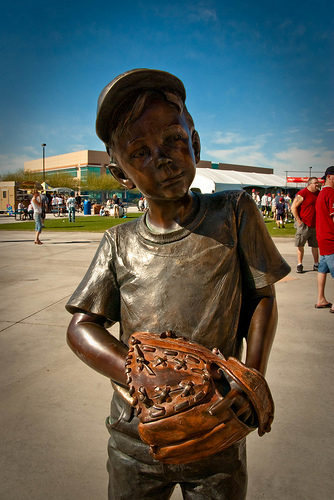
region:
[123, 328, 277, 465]
baseball mit on the statue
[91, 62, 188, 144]
hat on the boy's head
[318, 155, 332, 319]
man standing in the background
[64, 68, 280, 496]
copper color statue of a boy baseball player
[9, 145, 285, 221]
building in the background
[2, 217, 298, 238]
large green grassy field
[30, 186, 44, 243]
a woman standing on the sidewalk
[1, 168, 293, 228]
crowd of people in the distance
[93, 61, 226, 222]
the boy statue is looking to the right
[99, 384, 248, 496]
jean paths on the boy statue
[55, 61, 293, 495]
A statue of a young boy with a pitching glove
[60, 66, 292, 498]
Bronze statue of a young boy.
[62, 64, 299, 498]
Bronze statue of boy in baseball cap.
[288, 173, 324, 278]
Man in a red shirt standing with hand in his pocket.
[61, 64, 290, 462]
Statue of a boy with a baseball glove.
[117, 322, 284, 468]
Detailed baseball glove on a statue.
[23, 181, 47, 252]
Woman in white shirt standing with crossed arms.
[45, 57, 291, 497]
Statue with sunlight shining on the side.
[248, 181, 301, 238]
People standing around on green grass.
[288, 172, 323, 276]
Man in red shirt and glasses wearing tennis shoes.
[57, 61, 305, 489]
Bronze statue of boy in tee shirt and baseball cap.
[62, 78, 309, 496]
bronze statue with a baseball mitt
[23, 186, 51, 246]
woman in background in white tank top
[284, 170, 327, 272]
man in red shirt and gray shorts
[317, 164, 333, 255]
man in red shirt and backwards baseball hat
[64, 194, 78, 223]
person walking with white shirt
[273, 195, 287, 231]
person in black outfit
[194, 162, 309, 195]
white awning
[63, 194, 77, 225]
person wearing blue jeans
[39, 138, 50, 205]
light post in the distance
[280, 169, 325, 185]
red sign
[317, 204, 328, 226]
man wearing red shirt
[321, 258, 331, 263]
man wearing jean shorts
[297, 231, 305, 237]
man wearing grey shorts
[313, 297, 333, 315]
man wearing brown sandals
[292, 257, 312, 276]
man wearing black sneakers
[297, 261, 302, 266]
man wearing white socks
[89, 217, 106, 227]
green grass in field